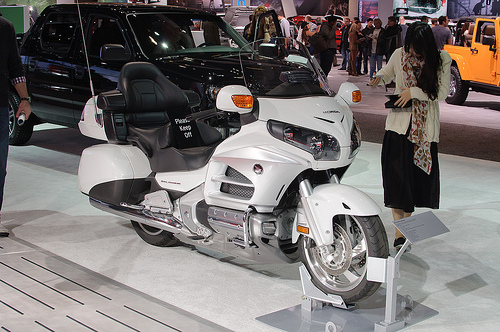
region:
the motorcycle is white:
[137, 102, 477, 252]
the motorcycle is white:
[215, 90, 395, 315]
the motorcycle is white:
[201, 115, 366, 235]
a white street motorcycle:
[76, 36, 386, 301]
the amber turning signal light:
[215, 81, 250, 111]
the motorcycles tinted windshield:
[236, 35, 331, 95]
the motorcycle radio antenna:
[75, 1, 98, 123]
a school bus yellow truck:
[444, 16, 499, 105]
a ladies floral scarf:
[402, 43, 433, 174]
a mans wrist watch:
[18, 93, 31, 103]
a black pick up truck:
[13, 0, 251, 80]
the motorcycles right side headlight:
[267, 119, 339, 162]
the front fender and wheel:
[292, 183, 390, 300]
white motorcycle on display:
[74, 50, 396, 295]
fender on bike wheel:
[305, 175, 381, 230]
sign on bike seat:
[160, 103, 212, 154]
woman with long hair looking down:
[387, 18, 450, 102]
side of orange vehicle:
[447, 13, 496, 88]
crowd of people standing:
[305, 11, 392, 78]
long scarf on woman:
[411, 80, 431, 172]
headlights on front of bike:
[273, 114, 348, 168]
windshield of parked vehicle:
[127, 9, 247, 66]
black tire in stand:
[286, 254, 354, 315]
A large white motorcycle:
[61, 27, 414, 309]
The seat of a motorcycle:
[103, 49, 220, 180]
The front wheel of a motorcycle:
[284, 173, 395, 328]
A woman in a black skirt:
[367, 19, 455, 261]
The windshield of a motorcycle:
[225, 27, 345, 117]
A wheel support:
[279, 175, 451, 330]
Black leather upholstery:
[92, 51, 239, 193]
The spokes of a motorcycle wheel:
[305, 208, 372, 298]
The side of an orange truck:
[455, 9, 498, 102]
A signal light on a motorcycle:
[208, 75, 260, 122]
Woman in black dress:
[381, 114, 442, 204]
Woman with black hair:
[400, 22, 447, 61]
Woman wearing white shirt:
[389, 52, 449, 105]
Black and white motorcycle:
[94, 67, 386, 297]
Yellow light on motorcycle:
[231, 93, 256, 110]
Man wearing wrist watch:
[13, 94, 38, 107]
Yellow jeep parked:
[447, 24, 491, 98]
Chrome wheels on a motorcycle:
[299, 215, 365, 295]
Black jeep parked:
[41, 3, 267, 111]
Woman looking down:
[400, 30, 441, 65]